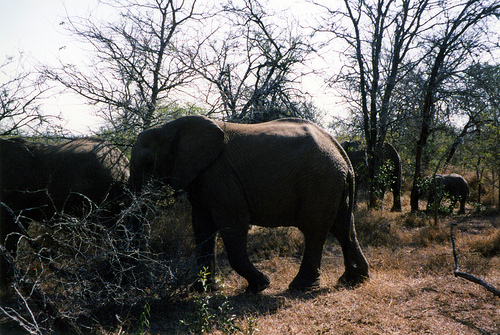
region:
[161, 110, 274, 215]
the elephants large ear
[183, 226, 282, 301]
the elephants bent knee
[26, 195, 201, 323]
the bare branches in front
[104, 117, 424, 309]
the main elephant in view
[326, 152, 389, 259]
the elephants tail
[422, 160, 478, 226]
the baby elephant in back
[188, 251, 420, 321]
the patch of ground the elephant is standing on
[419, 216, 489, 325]
the one branch on the right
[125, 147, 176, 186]
the closest elephant's eye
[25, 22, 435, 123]
the sky between the trees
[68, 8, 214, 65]
The trees have no leaves.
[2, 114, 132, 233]
Elephant in front of an Elephant.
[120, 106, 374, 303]
Black Elephant in the middle.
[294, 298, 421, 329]
The grass is brown.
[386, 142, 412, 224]
The trunk of an Elephant.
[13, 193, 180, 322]
The branches of a bush with no leaves.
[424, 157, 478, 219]
A small Elephant in the background.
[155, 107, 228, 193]
The ear of an Elephant.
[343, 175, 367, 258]
The tail of the Elephant.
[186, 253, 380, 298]
The feet of the Elephant.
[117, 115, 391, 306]
an elephant walking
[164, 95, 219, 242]
an elephant's ear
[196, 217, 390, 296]
an elephant's feet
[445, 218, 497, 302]
a dead tree on ground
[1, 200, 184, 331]
a dying shrub on side of path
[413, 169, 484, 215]
an elephant hiding behind tree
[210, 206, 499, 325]
a grassy field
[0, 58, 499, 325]
a bunch of elephants in forest setting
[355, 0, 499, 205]
a tree covering two elephants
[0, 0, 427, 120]
blue daylight sky in setting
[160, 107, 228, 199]
the ear of an elephant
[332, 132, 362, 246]
the tail of an elephant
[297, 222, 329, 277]
the leg of an elephant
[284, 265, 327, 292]
the foot of an elephant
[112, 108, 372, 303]
a large gray elephant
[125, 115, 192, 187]
the head of an elephant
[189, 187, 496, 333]
brown grass on the ground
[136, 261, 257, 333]
a small green plant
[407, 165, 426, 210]
the trunk of a tree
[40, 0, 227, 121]
the branches of a tree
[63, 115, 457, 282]
Elephants in the wilderness.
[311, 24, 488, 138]
The trees has no leaves.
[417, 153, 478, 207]
Baby elephant behind mother elephant.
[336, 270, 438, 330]
The grass is dry and brown.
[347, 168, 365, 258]
The elephant has a long tail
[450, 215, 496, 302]
A long branch sits on the ground.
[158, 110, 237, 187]
The elephant has big ears.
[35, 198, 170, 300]
The branch is bare.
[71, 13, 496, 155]
The sky is clear.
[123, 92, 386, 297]
The elephant is gray.